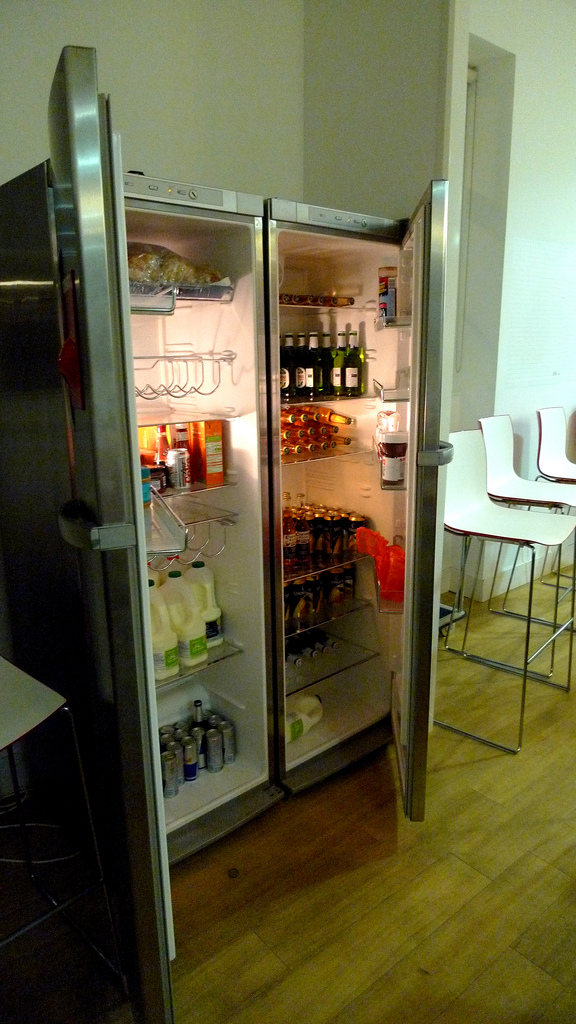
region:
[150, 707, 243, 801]
Energy drinks in the fridge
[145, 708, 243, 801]
Energy drinks are in the fridge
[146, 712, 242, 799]
Energy drinks in the refrigerator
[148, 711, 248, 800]
Energy drinks are in the refrigerator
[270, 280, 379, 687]
Beers in the fridge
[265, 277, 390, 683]
Beers are in the fridge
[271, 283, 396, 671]
Beers in the refrigerator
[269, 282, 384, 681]
Beers are in the refrigerator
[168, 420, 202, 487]
Bottle of ketchup in the fridge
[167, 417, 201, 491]
Bottle of ketchup in the refrigerator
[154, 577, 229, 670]
Gallons of milk on top of shelf.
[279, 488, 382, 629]
Two racks of beer in the fridge.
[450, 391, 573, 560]
Three white chairs on the side of the wall.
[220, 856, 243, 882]
Dark brown spot on the wood.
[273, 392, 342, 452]
Glass bottle on the rack in the fridge.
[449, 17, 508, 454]
Opening in the wall as an entrance.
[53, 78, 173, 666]
Silver part of the refrigerator door.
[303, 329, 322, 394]
Beer bottle in the fridge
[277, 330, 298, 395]
Beer bottle in the fridge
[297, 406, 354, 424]
Beer bottle in the fridge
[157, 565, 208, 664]
Gallon of milk in the fridge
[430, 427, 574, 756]
White stool next to the fridge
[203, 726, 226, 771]
Energy drink in the fridge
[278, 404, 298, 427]
Beer bottle in the fridge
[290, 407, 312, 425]
Beer bottle in the fridge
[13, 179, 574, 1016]
picture taken indoors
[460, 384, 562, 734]
white chairs on the wood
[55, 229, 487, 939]
the fridge doors are open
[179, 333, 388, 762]
the fridge is full of beverages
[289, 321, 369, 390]
the bottles are green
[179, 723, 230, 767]
red bull drinks on the bottom of the fridge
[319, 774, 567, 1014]
the floor is made of wood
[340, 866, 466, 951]
the wood is light brown in color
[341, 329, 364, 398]
a beer with a green bottle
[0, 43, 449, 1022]
an open steel refrigerator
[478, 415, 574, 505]
the seat of a white bar chair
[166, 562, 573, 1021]
the hardwood floor with chairs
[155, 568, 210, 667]
a bottle full of white liquid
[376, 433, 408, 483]
a bottle of nutella in the refrigerator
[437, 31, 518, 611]
a passage to another room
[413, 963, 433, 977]
a defect within the wood floor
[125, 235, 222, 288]
a bag of frozen meat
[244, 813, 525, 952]
the floors are wooden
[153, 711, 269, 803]
the cans are silver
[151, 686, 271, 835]
the cans are on the bottom shelf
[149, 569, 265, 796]
milk is above the cans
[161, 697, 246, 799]
group of cans in fridge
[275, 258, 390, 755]
a refrigerator full of beer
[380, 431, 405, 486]
a jar of nutella in the fridge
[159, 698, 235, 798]
bottle of beer surrounded by energy drinks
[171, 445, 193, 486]
a can of diet coke in a fridge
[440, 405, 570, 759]
three white bar height chairs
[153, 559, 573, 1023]
medium colored hardwood floor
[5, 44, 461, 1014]
stainless steel double door refrigerator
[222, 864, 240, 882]
dark brown knot in a piece of wood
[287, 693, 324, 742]
a jug laying on it's side in the bottom of the fridge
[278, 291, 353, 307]
a row of bottles all laying on their side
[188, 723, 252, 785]
several cans of red bull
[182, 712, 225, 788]
several cans of red bull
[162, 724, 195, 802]
several cans of red bull